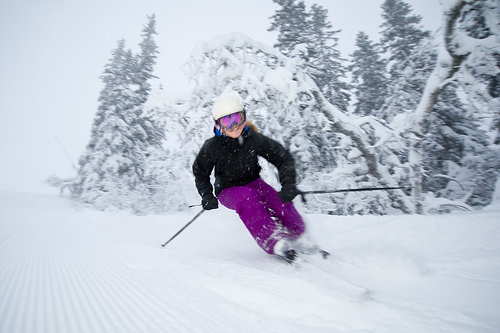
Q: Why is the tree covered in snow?
A: Because it has snowed recently.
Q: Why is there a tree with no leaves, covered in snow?
A: Because the tree had lost it's leaves for the winter months and it had snowed on the tree and not melted.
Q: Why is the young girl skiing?
A: She enjoys skiing.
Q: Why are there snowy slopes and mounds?
A: It has snowed recently and piles had accumulated.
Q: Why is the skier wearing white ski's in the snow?
A: The person liked the color of the ski's.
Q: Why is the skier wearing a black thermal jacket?
A: Because the skier liked the color of the jacket.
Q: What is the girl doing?
A: Skiing.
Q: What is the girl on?
A: Skis.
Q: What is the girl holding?
A: Ski poles.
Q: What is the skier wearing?
A: A black jacket.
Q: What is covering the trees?
A: Snow.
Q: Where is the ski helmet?
A: On the skier's head.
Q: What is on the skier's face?
A: Ski goggles.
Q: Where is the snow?
A: On the ground and trees.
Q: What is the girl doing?
A: Skiing.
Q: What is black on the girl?
A: A jacket.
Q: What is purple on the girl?
A: Pants.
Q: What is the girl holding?
A: Ski poles.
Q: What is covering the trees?
A: Snow.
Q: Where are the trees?
A: Behind the girl.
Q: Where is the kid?
A: On the snow.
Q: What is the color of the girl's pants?
A: Purple.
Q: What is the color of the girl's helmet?
A: White.